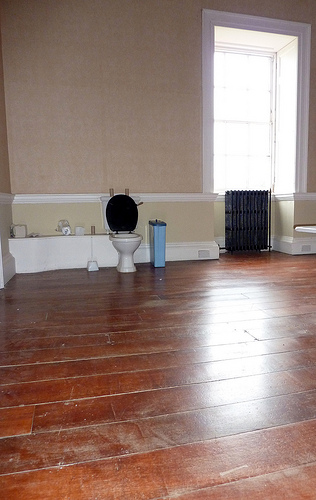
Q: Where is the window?
A: Above the heater.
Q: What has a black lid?
A: Toilet.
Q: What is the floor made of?
A: Wood.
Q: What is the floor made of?
A: Wood.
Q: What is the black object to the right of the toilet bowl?
A: A radiator.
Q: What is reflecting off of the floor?
A: A sun glare.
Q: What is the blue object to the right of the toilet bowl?
A: A garbage can.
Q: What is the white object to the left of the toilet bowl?
A: A toilet bowl brush.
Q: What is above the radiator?
A: A tall window.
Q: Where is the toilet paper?
A: To the left of the toilet and on the wall.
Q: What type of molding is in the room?
A: Crown molding.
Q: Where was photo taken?
A: Bathroom.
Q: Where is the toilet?
A: On the floor.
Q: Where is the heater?
A: By the window.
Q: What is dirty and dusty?
A: Floor.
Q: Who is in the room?
A: No one.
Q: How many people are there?
A: None.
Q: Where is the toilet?
A: Far end of the room.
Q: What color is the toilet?
A: White.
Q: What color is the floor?
A: Reddish brown.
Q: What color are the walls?
A: Tan.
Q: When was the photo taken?
A: Daytime.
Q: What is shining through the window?
A: Light.